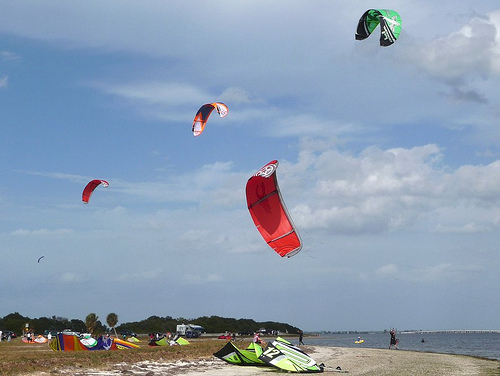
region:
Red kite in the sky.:
[235, 153, 306, 260]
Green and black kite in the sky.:
[350, 2, 402, 52]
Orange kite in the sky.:
[184, 91, 231, 143]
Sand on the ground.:
[182, 340, 497, 374]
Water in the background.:
[220, 325, 499, 365]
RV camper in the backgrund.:
[174, 318, 208, 338]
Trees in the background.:
[1, 306, 308, 343]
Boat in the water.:
[349, 330, 366, 345]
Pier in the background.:
[388, 324, 498, 338]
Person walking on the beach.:
[293, 324, 308, 344]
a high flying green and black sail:
[352, 7, 402, 47]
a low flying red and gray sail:
[245, 156, 305, 261]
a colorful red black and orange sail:
[189, 100, 229, 136]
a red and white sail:
[79, 175, 109, 205]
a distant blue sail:
[36, 254, 46, 263]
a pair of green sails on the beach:
[214, 329, 325, 372]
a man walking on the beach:
[388, 326, 399, 347]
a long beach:
[323, 329, 497, 371]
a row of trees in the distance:
[0, 313, 297, 335]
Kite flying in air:
[355, 7, 403, 48]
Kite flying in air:
[247, 161, 306, 260]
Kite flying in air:
[190, 99, 226, 139]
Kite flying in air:
[81, 175, 111, 202]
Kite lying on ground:
[216, 337, 323, 374]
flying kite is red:
[243, 160, 305, 255]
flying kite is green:
[353, 6, 402, 47]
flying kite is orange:
[190, 104, 227, 132]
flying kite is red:
[81, 179, 109, 204]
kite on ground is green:
[219, 334, 324, 371]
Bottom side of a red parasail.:
[238, 158, 309, 260]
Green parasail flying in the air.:
[354, 6, 404, 48]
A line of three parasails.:
[65, 7, 405, 204]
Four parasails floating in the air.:
[77, 7, 402, 279]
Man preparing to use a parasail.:
[385, 326, 401, 350]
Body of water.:
[207, 326, 497, 362]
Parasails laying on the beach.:
[52, 324, 344, 373]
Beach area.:
[6, 333, 498, 375]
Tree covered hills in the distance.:
[1, 308, 304, 337]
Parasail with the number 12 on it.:
[210, 334, 327, 374]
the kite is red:
[246, 160, 305, 260]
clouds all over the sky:
[0, 0, 497, 285]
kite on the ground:
[215, 337, 315, 374]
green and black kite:
[356, 6, 400, 45]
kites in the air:
[82, 6, 401, 258]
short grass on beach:
[0, 340, 307, 373]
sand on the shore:
[317, 345, 499, 372]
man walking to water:
[390, 330, 397, 348]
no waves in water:
[280, 335, 498, 355]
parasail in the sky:
[228, 153, 325, 266]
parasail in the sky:
[78, 162, 118, 222]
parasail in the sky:
[171, 76, 226, 137]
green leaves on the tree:
[216, 301, 242, 335]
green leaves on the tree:
[283, 316, 300, 339]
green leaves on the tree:
[248, 314, 261, 339]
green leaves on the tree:
[98, 297, 135, 335]